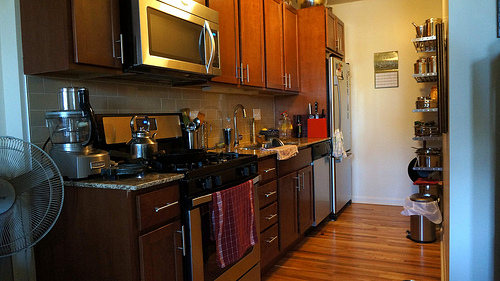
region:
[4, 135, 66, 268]
the fan is next to the window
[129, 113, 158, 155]
the kettle on the stove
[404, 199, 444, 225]
the trash bag in the can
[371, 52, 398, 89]
the calender on the wall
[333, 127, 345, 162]
the towel on the fridge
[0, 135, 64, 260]
a standing pedestal fan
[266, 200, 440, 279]
hardwood floor in the kitchen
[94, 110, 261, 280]
a stainless steel oven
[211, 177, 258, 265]
red towel hanging on the oven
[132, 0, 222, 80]
a stainless steel microwave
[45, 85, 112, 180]
a food processor on the counter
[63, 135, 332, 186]
granite counter top in the kitchen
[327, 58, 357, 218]
stainless steel refrigerator in the corner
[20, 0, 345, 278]
hardwood cabinets in the kitchen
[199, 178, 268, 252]
a towel hanging on oven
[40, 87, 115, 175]
a food processor on counter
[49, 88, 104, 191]
a silver food processor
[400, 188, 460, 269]
a trash can inside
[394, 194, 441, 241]
a small trash can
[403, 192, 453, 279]
a silver trash can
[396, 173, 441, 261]
a silver garbage can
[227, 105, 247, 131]
a silver sink faucet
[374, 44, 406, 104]
a calendar on the wall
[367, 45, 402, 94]
a calendar is hanging on the wall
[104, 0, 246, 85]
a microwave oven over the stove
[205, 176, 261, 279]
a red and white checked towel hanging on oven door handle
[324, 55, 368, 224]
stainless steal refrigerator with bottom freezer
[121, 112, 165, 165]
silver tea pot on the stove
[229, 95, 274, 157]
tall kitchen facet in sink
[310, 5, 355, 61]
wooden cabinet over the refrigator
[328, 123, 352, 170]
kitchen towel on refrigerator handle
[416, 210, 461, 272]
a silver garbage can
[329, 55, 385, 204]
a silver kitchen fridge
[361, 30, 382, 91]
a calendar on teh wall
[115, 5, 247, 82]
a silver kitchen microwave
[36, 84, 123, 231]
a silver food processor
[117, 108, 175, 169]
a silver tea pot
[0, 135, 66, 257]
white metal fan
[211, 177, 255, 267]
red dish towel on the stove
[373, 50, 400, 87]
gold and white wall calendar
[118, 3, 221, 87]
silver and black microwave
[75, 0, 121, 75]
a door for a cabinet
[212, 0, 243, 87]
a door for a cabinet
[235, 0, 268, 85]
a door for a cabinet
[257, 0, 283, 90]
a door for a cabinet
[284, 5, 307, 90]
a door for a cabinet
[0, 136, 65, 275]
A fan on the side of the cabinets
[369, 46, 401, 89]
Calendar on the wall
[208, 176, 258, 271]
Dish towel hanging from the oven handle.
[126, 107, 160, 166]
Tea pot on the stove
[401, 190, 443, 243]
Steel trash can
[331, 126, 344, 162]
Towel hanging from the refrigerator handle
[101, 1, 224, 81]
Microwave oven above the stovetop.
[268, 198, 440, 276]
Wooden panels on the floor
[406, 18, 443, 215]
a filled pantry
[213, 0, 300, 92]
Wooden cabinets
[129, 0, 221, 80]
Microwave oven in a kitchen.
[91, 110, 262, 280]
Gas cooking oven in a kitchen.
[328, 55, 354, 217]
Grey refrigerator in a kitchen.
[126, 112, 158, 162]
Grey kettle on stovetop in a kitchen.